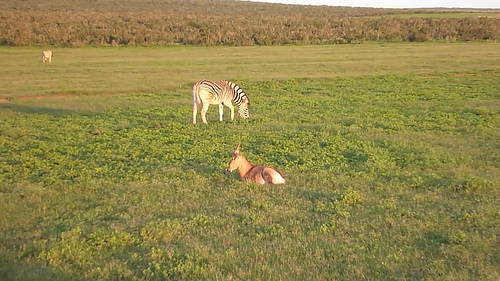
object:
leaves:
[373, 10, 418, 40]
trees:
[433, 20, 467, 43]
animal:
[192, 79, 250, 125]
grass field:
[0, 41, 500, 278]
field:
[0, 0, 499, 278]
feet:
[219, 119, 224, 121]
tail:
[195, 86, 202, 106]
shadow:
[3, 101, 98, 118]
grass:
[316, 129, 468, 233]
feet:
[192, 122, 197, 126]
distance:
[0, 0, 500, 47]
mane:
[231, 82, 250, 105]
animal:
[40, 49, 52, 62]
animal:
[226, 142, 286, 185]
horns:
[235, 140, 241, 153]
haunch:
[255, 168, 284, 183]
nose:
[226, 169, 229, 171]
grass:
[58, 174, 457, 263]